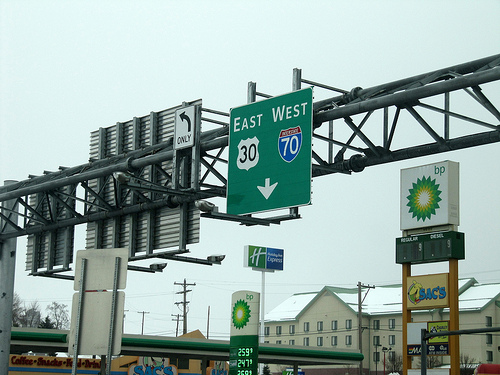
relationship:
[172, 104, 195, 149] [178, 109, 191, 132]
sign has left arrow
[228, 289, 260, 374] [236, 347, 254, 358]
bp sign has price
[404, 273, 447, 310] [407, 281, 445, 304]
sac's sign has logo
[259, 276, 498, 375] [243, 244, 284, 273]
hotel has sign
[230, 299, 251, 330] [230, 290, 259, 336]
logo has background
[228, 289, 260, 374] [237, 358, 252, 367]
bp sign has price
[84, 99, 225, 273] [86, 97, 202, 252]
highway sign has back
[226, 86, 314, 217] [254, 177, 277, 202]
sign has down arrow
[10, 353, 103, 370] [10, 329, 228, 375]
letters on building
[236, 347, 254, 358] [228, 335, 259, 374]
price has background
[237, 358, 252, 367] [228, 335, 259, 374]
price has background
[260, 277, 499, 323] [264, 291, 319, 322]
roof has snow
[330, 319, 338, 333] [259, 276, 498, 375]
window on hotel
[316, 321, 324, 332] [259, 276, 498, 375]
window on hotel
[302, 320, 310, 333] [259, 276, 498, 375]
window on hotel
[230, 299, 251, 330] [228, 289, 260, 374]
logo on bp sign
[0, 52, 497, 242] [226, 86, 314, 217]
beam holding sign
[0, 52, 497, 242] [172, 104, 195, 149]
beam holding sign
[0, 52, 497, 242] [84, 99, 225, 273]
beam holding highway sign